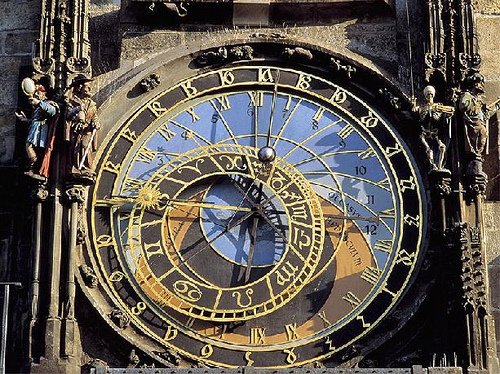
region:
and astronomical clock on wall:
[67, 30, 434, 372]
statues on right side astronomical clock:
[384, 70, 495, 233]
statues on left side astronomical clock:
[7, 68, 133, 193]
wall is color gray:
[3, 7, 497, 370]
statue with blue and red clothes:
[11, 67, 56, 182]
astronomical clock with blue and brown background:
[80, 35, 428, 361]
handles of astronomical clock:
[91, 182, 375, 306]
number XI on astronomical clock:
[336, 275, 366, 321]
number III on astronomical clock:
[336, 120, 356, 141]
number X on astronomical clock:
[183, 101, 203, 126]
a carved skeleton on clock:
[406, 64, 463, 202]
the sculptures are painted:
[12, 51, 99, 205]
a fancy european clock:
[96, 90, 428, 369]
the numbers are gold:
[88, 104, 213, 234]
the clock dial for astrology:
[111, 135, 363, 367]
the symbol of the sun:
[125, 169, 191, 215]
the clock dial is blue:
[116, 87, 392, 360]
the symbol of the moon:
[242, 135, 290, 182]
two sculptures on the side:
[14, 81, 109, 195]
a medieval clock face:
[12, 29, 488, 349]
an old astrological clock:
[67, 50, 442, 365]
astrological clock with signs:
[60, 55, 430, 366]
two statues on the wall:
[396, 65, 496, 205]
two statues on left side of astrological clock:
[5, 67, 105, 193]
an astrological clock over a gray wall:
[3, 2, 491, 366]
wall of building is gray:
[6, 6, 499, 371]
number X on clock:
[311, 302, 336, 334]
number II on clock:
[336, 118, 356, 144]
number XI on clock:
[338, 285, 365, 315]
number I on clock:
[279, 94, 298, 114]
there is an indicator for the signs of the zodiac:
[127, 143, 327, 322]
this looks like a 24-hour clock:
[110, 83, 408, 355]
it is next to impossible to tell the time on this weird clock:
[83, 63, 426, 371]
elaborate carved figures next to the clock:
[408, 78, 496, 194]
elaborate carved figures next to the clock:
[11, 68, 102, 189]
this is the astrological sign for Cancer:
[169, 276, 205, 303]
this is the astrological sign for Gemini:
[140, 237, 168, 262]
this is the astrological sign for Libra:
[289, 220, 316, 256]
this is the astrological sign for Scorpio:
[285, 199, 313, 224]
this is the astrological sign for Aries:
[173, 154, 211, 178]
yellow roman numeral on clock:
[244, 87, 267, 108]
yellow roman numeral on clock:
[281, 95, 294, 114]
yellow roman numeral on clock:
[312, 102, 325, 122]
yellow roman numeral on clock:
[337, 118, 356, 141]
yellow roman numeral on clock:
[356, 146, 375, 160]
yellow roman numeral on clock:
[375, 204, 397, 221]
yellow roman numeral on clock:
[372, 234, 393, 254]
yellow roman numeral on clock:
[359, 265, 385, 285]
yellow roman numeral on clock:
[342, 289, 362, 306]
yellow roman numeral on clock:
[282, 322, 301, 341]